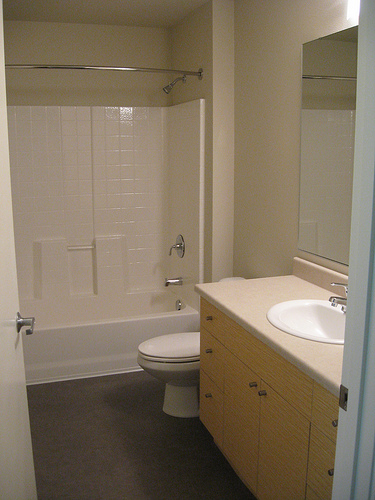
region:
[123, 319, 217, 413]
white toilet in bathroom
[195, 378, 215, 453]
wood cabinet in bathroom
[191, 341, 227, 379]
wood cabinet in bathroom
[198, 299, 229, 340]
wood cabinet in bathroom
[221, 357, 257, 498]
wood cabinet in bathroom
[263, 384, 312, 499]
wood cabinet in bathroom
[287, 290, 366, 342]
white sink on cabinets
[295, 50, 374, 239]
mirror on right wall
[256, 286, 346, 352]
white bathroom sink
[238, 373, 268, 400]
silver metal bathroom cabinet handles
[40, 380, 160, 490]
grey carpet on bathroom floor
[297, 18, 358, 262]
large mirror hanging above bathroom sink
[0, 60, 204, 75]
silver metal shower bar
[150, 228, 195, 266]
silver metal shower handle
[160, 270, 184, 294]
silver bathroom tub faucet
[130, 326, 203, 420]
white bathroom toilet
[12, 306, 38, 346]
silver metal bathroom door handle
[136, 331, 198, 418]
a white porcelain toilet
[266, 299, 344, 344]
a white porcelain bathroom sink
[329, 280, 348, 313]
chrome bathroom sink faucet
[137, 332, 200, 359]
a plastic white toilet seat lid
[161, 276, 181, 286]
a chrome bathtub faucet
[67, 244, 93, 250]
a clear plastic towel bar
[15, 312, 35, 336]
a chrome door handle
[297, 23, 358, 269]
a wall mounted bathroom mirror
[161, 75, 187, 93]
a bathroom shower head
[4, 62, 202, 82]
a shower curtain rod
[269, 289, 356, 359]
the sink is clean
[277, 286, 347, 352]
the sink is clean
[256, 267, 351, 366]
the sink is clean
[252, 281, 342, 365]
the sink is clean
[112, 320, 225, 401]
toilet lid is closed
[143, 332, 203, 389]
toilet lid is closed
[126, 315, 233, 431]
toilet lid is closed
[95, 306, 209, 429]
toilet lid is closed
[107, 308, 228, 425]
toilet lid is closed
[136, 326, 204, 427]
white toilet in bathroom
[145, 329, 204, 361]
white toilet seat in bathroom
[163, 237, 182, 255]
silver faucet in shower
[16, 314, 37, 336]
silver handle on door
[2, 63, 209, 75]
silver shower curtain rail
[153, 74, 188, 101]
silver shower head in bathroom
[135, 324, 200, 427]
white base on toilet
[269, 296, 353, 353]
white sink in bathroom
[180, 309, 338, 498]
brown cabinets in bathroom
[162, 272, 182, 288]
silver faucet in the bathroom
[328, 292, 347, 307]
silver faucet in the bathroom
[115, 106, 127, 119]
A tile in a wall.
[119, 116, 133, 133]
A tile in a wall.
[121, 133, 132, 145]
A tile in a wall.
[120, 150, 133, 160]
A tile in a wall.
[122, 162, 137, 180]
A tile in a wall.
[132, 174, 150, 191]
A tile in a wall.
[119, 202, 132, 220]
A tile in a wall.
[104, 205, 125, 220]
A tile in a wall.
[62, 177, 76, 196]
A tile in a wall.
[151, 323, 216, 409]
a toilet in the bathroom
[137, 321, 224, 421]
a white toilet in the bathroom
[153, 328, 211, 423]
a toilet is white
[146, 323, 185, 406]
a bathroom toilet is white